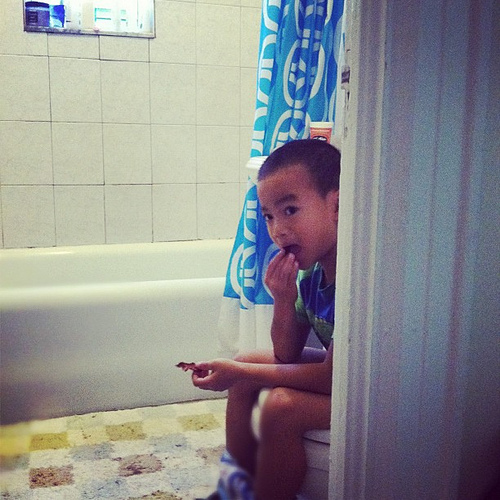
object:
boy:
[191, 139, 340, 499]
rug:
[1, 396, 229, 499]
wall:
[0, 1, 265, 247]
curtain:
[221, 1, 346, 312]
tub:
[2, 237, 240, 426]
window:
[20, 1, 157, 38]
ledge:
[22, 22, 159, 39]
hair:
[258, 138, 340, 194]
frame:
[325, 0, 468, 500]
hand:
[191, 357, 237, 393]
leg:
[219, 362, 270, 471]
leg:
[244, 389, 331, 500]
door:
[327, 2, 500, 500]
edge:
[327, 1, 366, 499]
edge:
[2, 238, 239, 262]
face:
[257, 173, 329, 269]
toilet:
[251, 391, 334, 499]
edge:
[305, 440, 329, 473]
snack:
[174, 361, 205, 373]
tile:
[101, 59, 149, 122]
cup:
[308, 119, 332, 143]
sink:
[245, 153, 268, 184]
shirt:
[291, 263, 337, 350]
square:
[28, 464, 72, 489]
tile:
[50, 120, 103, 187]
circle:
[282, 37, 325, 108]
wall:
[452, 6, 496, 497]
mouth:
[280, 242, 302, 256]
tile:
[149, 123, 195, 185]